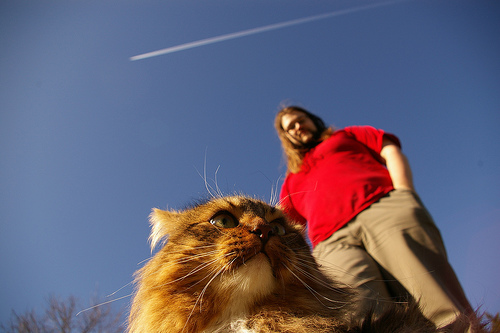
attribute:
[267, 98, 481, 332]
man — standing, looking, blonde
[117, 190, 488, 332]
cat — brown, furry, orange, fluffy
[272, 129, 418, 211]
shirt — red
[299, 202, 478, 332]
pants — brown, tan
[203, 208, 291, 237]
eyes — yellows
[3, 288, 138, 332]
tree — bare